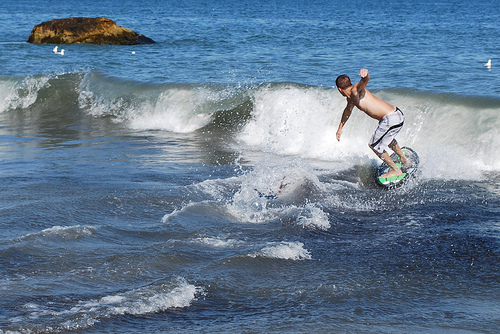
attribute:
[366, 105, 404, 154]
boardshorts — white, black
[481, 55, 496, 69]
bird — white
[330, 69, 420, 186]
surfer — one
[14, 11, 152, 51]
rock — large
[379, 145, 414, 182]
surfboard — one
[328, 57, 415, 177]
man — one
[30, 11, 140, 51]
rock — big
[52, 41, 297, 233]
water — some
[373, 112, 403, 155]
trunks — white, swim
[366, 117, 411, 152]
stripe — black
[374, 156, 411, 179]
feet — human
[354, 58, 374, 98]
arm — one, male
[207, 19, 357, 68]
water — calm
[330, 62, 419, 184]
man — one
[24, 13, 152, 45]
rock — brown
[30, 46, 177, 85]
water — some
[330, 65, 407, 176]
man — one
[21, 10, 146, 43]
rock — one, brown 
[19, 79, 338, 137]
wave — large 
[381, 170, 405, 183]
green — neon 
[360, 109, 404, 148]
shorts — black , white , surf 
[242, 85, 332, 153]
wave — large 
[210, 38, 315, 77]
water — blue , dark 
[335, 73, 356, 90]
hair — dark , short 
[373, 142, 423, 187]
surfboard — one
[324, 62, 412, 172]
man — one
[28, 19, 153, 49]
rock — one, small 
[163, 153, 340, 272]
caps — white 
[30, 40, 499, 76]
birds — some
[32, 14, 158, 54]
formation — rock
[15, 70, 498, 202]
wave — small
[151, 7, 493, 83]
water — calm, in the daytime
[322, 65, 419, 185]
boy — is surfing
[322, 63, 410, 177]
boy — is surfing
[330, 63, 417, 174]
boy — is surfing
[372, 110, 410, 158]
shorts — gray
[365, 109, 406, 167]
shorts — gray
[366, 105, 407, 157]
shorts — gray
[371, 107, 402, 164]
shorts — gray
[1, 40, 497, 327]
water — ocean